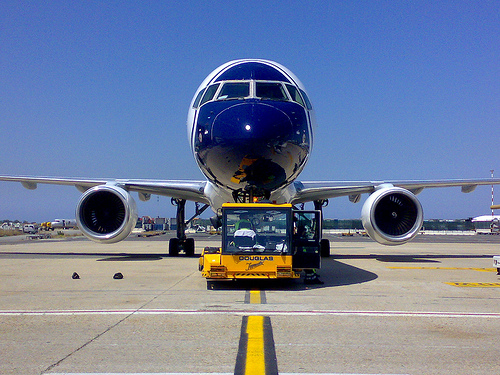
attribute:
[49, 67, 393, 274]
plane — blue, white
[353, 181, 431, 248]
engine — large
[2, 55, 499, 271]
plane — large, blue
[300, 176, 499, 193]
wing — long, white, silver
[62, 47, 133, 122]
sky — clear, blue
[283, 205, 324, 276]
door — open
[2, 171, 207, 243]
wing — long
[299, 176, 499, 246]
wing — white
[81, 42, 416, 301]
airplane — blue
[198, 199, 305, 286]
vehicle — yellow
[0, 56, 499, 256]
jet — large, blue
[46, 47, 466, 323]
plane — blue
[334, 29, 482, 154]
blue sky — cloudless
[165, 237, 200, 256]
wheel — large, rubber, black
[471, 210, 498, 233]
hanger — white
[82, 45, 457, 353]
jet — large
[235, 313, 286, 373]
line — large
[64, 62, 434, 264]
plane — blue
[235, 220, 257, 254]
person — driver, sitting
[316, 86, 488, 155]
cloud — clear, blue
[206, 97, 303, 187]
nose — blue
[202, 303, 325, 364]
stripe — black and yellow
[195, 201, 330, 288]
cart — yellow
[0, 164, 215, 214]
wing — long, white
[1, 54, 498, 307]
plane — large, blue, white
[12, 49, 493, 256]
airplane — large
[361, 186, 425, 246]
engine — large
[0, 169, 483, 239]
wing — long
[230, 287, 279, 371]
stripe — yellow and black